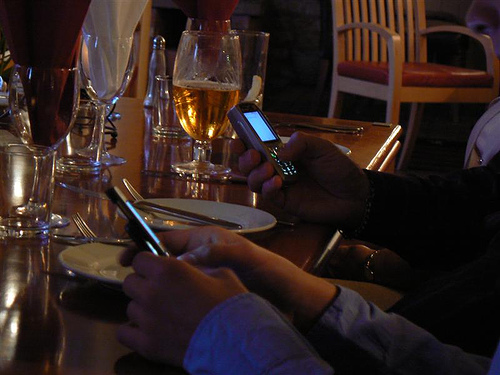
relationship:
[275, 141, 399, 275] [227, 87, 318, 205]
man holding phone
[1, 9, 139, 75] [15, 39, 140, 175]
napkin in glass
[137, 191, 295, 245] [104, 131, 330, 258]
plate on table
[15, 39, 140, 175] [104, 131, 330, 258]
glass on table